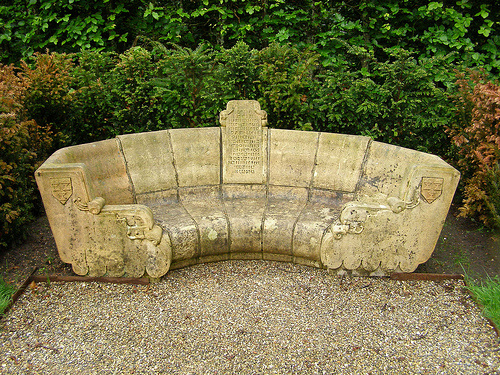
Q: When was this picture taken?
A: Late afternoon.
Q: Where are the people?
A: There are no people.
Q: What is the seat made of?
A: It's made of stone.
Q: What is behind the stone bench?
A: Trees and bushes.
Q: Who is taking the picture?
A: A photographer.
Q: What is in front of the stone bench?
A: Gravel and rocks.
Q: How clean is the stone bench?
A: It is very dirty.